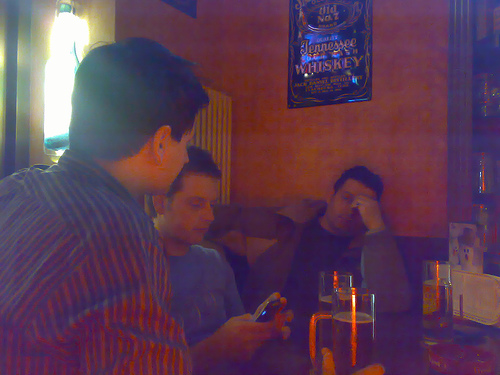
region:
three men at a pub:
[0, 12, 494, 372]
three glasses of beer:
[278, 257, 453, 362]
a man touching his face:
[281, 170, 391, 290]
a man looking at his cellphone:
[132, 136, 292, 356]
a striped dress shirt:
[0, 155, 180, 365]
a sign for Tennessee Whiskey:
[270, 2, 380, 117]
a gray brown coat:
[222, 215, 404, 311]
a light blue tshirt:
[140, 240, 255, 351]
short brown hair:
[57, 30, 212, 171]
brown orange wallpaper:
[244, 25, 453, 230]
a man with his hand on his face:
[241, 169, 418, 308]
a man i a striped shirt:
[1, 78, 206, 368]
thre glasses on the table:
[300, 249, 475, 367]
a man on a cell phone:
[152, 153, 296, 368]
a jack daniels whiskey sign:
[265, 7, 399, 117]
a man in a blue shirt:
[131, 153, 295, 365]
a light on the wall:
[1, 1, 115, 164]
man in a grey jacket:
[231, 164, 408, 308]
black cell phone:
[213, 289, 307, 356]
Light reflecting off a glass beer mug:
[326, 280, 377, 356]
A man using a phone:
[242, 276, 285, 332]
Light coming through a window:
[30, 6, 117, 157]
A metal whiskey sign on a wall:
[284, 7, 386, 106]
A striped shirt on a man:
[10, 160, 193, 362]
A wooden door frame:
[441, 20, 486, 220]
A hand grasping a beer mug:
[308, 281, 378, 373]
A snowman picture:
[437, 211, 493, 320]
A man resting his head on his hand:
[318, 154, 408, 280]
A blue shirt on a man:
[164, 233, 246, 334]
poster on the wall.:
[287, 12, 367, 107]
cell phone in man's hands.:
[254, 293, 280, 320]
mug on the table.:
[327, 292, 374, 354]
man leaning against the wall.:
[295, 158, 414, 263]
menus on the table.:
[458, 273, 495, 318]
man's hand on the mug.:
[313, 349, 391, 372]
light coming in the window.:
[50, 29, 75, 123]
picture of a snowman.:
[453, 231, 478, 264]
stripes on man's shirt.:
[40, 222, 115, 300]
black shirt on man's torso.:
[307, 240, 343, 262]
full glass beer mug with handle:
[302, 280, 369, 374]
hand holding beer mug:
[319, 343, 391, 373]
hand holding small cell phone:
[250, 286, 297, 340]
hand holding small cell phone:
[210, 294, 277, 363]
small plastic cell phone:
[251, 295, 278, 326]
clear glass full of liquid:
[424, 260, 452, 342]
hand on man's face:
[327, 161, 387, 233]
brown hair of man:
[160, 138, 220, 198]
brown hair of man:
[329, 161, 384, 198]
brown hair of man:
[72, 41, 207, 158]